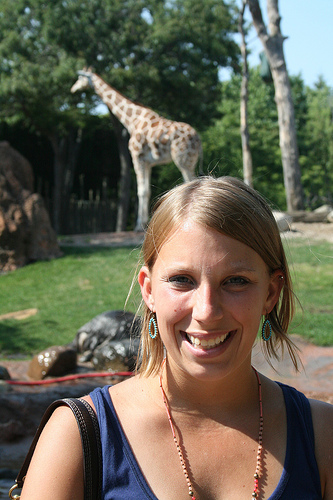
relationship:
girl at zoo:
[18, 174, 333, 498] [3, 6, 332, 462]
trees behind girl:
[228, 9, 325, 234] [18, 174, 333, 498]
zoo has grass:
[3, 6, 332, 462] [7, 269, 113, 304]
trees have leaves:
[4, 8, 88, 247] [5, 5, 223, 71]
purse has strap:
[8, 384, 124, 496] [20, 393, 104, 428]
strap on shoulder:
[20, 393, 104, 428] [33, 357, 156, 432]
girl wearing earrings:
[18, 174, 333, 498] [145, 310, 161, 348]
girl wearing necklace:
[18, 174, 333, 498] [154, 355, 273, 500]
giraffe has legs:
[67, 62, 208, 248] [123, 140, 159, 241]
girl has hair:
[18, 174, 333, 498] [127, 166, 298, 265]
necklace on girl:
[154, 355, 273, 500] [18, 174, 333, 498]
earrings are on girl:
[145, 310, 161, 348] [18, 174, 333, 498]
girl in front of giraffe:
[18, 174, 333, 498] [67, 62, 208, 248]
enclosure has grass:
[3, 6, 332, 462] [7, 269, 113, 304]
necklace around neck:
[154, 355, 273, 500] [147, 338, 282, 385]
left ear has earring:
[128, 264, 161, 318] [145, 310, 161, 348]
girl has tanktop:
[18, 174, 333, 498] [78, 371, 327, 498]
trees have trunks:
[228, 9, 325, 234] [239, 158, 314, 223]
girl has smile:
[18, 174, 333, 498] [173, 320, 247, 360]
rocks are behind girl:
[22, 299, 144, 383] [18, 174, 333, 498]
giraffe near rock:
[67, 62, 208, 248] [23, 332, 80, 382]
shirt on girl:
[78, 371, 327, 498] [18, 174, 333, 498]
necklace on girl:
[154, 355, 273, 500] [102, 171, 297, 498]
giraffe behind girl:
[67, 62, 208, 248] [18, 174, 333, 498]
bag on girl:
[8, 384, 124, 496] [18, 174, 333, 498]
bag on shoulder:
[8, 384, 124, 496] [33, 357, 156, 432]